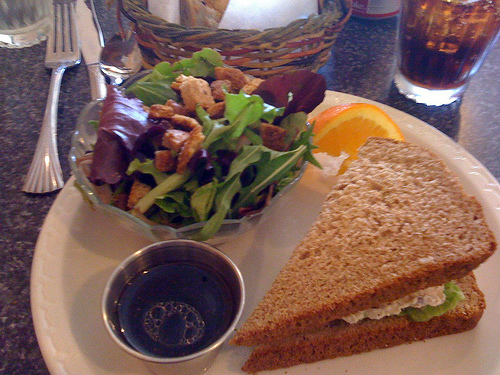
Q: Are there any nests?
A: No, there are no nests.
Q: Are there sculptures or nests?
A: No, there are no nests or sculptures.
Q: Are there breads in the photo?
A: Yes, there is a bread.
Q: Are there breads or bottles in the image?
A: Yes, there is a bread.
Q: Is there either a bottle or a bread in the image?
A: Yes, there is a bread.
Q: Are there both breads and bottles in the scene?
A: No, there is a bread but no bottles.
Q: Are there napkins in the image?
A: No, there are no napkins.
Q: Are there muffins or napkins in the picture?
A: No, there are no napkins or muffins.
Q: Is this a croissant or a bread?
A: This is a bread.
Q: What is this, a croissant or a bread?
A: This is a bread.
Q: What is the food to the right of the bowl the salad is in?
A: The food is a bread.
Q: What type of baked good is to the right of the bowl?
A: The food is a bread.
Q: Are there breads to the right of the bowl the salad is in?
A: Yes, there is a bread to the right of the bowl.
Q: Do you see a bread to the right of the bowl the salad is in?
A: Yes, there is a bread to the right of the bowl.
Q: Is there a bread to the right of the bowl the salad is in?
A: Yes, there is a bread to the right of the bowl.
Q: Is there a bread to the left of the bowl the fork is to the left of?
A: No, the bread is to the right of the bowl.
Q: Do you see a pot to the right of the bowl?
A: No, there is a bread to the right of the bowl.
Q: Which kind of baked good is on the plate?
A: The food is a bread.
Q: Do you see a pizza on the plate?
A: No, there is a bread on the plate.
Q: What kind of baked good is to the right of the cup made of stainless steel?
A: The food is a bread.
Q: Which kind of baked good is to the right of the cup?
A: The food is a bread.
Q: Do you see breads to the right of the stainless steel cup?
A: Yes, there is a bread to the right of the cup.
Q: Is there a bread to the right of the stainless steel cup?
A: Yes, there is a bread to the right of the cup.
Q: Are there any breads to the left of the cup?
A: No, the bread is to the right of the cup.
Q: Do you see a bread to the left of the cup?
A: No, the bread is to the right of the cup.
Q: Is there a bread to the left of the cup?
A: No, the bread is to the right of the cup.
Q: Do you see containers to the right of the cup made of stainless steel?
A: No, there is a bread to the right of the cup.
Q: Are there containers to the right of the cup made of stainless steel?
A: No, there is a bread to the right of the cup.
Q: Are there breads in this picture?
A: Yes, there is a bread.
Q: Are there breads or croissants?
A: Yes, there is a bread.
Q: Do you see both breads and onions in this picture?
A: No, there is a bread but no onions.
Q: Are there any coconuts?
A: No, there are no coconuts.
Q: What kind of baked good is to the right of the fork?
A: The food is a bread.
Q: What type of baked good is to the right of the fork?
A: The food is a bread.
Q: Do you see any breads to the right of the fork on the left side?
A: Yes, there is a bread to the right of the fork.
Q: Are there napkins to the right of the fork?
A: No, there is a bread to the right of the fork.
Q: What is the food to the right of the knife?
A: The food is a bread.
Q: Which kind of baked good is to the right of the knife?
A: The food is a bread.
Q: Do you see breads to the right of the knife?
A: Yes, there is a bread to the right of the knife.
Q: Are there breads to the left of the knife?
A: No, the bread is to the right of the knife.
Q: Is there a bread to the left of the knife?
A: No, the bread is to the right of the knife.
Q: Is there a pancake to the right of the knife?
A: No, there is a bread to the right of the knife.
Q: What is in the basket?
A: The bread is in the basket.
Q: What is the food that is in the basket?
A: The food is a bread.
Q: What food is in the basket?
A: The food is a bread.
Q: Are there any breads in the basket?
A: Yes, there is a bread in the basket.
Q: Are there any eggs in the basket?
A: No, there is a bread in the basket.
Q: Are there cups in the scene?
A: Yes, there is a cup.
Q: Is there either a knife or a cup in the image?
A: Yes, there is a cup.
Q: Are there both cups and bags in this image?
A: No, there is a cup but no bags.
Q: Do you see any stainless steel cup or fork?
A: Yes, there is a stainless steel cup.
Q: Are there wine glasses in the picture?
A: No, there are no wine glasses.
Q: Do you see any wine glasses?
A: No, there are no wine glasses.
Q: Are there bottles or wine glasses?
A: No, there are no wine glasses or bottles.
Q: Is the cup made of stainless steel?
A: Yes, the cup is made of stainless steel.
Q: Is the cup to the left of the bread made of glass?
A: No, the cup is made of stainless steel.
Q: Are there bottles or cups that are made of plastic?
A: No, there is a cup but it is made of stainless steel.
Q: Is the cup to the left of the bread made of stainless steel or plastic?
A: The cup is made of stainless steel.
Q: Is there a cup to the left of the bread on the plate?
A: Yes, there is a cup to the left of the bread.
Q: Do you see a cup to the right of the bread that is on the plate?
A: No, the cup is to the left of the bread.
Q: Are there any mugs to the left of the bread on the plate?
A: No, there is a cup to the left of the bread.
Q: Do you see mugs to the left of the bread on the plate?
A: No, there is a cup to the left of the bread.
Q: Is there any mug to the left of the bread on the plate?
A: No, there is a cup to the left of the bread.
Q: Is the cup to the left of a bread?
A: Yes, the cup is to the left of a bread.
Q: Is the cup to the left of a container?
A: No, the cup is to the left of a bread.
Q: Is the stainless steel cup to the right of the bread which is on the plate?
A: No, the cup is to the left of the bread.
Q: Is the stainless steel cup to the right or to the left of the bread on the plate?
A: The cup is to the left of the bread.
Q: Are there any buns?
A: No, there are no buns.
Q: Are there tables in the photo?
A: Yes, there is a table.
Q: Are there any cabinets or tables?
A: Yes, there is a table.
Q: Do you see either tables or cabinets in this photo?
A: Yes, there is a table.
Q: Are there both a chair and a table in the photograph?
A: No, there is a table but no chairs.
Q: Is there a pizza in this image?
A: No, there are no pizzas.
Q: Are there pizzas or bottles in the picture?
A: No, there are no pizzas or bottles.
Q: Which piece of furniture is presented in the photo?
A: The piece of furniture is a table.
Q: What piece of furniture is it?
A: The piece of furniture is a table.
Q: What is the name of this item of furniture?
A: That is a table.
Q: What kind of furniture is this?
A: That is a table.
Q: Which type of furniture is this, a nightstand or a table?
A: That is a table.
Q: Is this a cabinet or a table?
A: This is a table.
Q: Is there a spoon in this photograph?
A: Yes, there is a spoon.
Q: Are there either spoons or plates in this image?
A: Yes, there is a spoon.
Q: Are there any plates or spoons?
A: Yes, there is a spoon.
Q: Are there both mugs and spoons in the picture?
A: No, there is a spoon but no mugs.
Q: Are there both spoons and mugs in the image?
A: No, there is a spoon but no mugs.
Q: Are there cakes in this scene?
A: No, there are no cakes.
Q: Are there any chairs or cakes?
A: No, there are no cakes or chairs.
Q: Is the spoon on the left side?
A: Yes, the spoon is on the left of the image.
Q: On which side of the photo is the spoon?
A: The spoon is on the left of the image.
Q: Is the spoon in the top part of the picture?
A: Yes, the spoon is in the top of the image.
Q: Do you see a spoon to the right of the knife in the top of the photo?
A: Yes, there is a spoon to the right of the knife.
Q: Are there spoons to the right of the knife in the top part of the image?
A: Yes, there is a spoon to the right of the knife.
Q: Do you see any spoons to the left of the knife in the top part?
A: No, the spoon is to the right of the knife.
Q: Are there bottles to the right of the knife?
A: No, there is a spoon to the right of the knife.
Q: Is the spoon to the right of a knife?
A: Yes, the spoon is to the right of a knife.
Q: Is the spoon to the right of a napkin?
A: No, the spoon is to the right of a knife.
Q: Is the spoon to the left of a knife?
A: No, the spoon is to the right of a knife.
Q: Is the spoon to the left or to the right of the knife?
A: The spoon is to the right of the knife.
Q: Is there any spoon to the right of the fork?
A: Yes, there is a spoon to the right of the fork.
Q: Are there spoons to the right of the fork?
A: Yes, there is a spoon to the right of the fork.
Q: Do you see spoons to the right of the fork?
A: Yes, there is a spoon to the right of the fork.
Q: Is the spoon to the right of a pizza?
A: No, the spoon is to the right of the fork.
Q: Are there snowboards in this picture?
A: No, there are no snowboards.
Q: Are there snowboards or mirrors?
A: No, there are no snowboards or mirrors.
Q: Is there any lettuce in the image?
A: Yes, there is lettuce.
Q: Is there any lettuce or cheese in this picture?
A: Yes, there is lettuce.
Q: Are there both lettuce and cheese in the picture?
A: No, there is lettuce but no cheese.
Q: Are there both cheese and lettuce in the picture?
A: No, there is lettuce but no cheese.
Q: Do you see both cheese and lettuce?
A: No, there is lettuce but no cheese.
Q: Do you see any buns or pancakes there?
A: No, there are no buns or pancakes.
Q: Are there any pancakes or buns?
A: No, there are no buns or pancakes.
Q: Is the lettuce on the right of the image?
A: Yes, the lettuce is on the right of the image.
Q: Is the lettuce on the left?
A: No, the lettuce is on the right of the image.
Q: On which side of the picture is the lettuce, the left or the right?
A: The lettuce is on the right of the image.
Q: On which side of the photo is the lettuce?
A: The lettuce is on the right of the image.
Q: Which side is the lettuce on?
A: The lettuce is on the right of the image.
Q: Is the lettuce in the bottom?
A: Yes, the lettuce is in the bottom of the image.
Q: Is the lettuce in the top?
A: No, the lettuce is in the bottom of the image.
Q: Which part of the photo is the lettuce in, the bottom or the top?
A: The lettuce is in the bottom of the image.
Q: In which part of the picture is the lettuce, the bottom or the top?
A: The lettuce is in the bottom of the image.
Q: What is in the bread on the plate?
A: The lettuce is in the bread.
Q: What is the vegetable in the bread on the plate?
A: The vegetable is lettuce.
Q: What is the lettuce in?
A: The lettuce is in the bread.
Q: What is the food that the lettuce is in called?
A: The food is a bread.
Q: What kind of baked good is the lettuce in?
A: The lettuce is in the bread.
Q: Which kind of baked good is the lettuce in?
A: The lettuce is in the bread.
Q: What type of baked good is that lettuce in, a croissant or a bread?
A: The lettuce is in a bread.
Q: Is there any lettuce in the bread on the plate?
A: Yes, there is lettuce in the bread.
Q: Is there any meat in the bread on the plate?
A: No, there is lettuce in the bread.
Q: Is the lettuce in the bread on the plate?
A: Yes, the lettuce is in the bread.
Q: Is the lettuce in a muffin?
A: No, the lettuce is in the bread.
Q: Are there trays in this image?
A: No, there are no trays.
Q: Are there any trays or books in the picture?
A: No, there are no trays or books.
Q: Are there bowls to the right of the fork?
A: Yes, there is a bowl to the right of the fork.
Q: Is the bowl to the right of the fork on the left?
A: Yes, the bowl is to the right of the fork.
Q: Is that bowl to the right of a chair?
A: No, the bowl is to the right of the fork.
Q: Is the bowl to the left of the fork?
A: No, the bowl is to the right of the fork.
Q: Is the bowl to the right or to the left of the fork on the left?
A: The bowl is to the right of the fork.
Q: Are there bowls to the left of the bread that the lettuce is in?
A: Yes, there is a bowl to the left of the bread.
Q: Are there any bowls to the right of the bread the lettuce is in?
A: No, the bowl is to the left of the bread.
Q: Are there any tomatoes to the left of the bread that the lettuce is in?
A: No, there is a bowl to the left of the bread.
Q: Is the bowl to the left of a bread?
A: Yes, the bowl is to the left of a bread.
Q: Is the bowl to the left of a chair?
A: No, the bowl is to the left of a bread.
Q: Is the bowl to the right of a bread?
A: No, the bowl is to the left of a bread.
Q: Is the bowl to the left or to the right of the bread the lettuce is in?
A: The bowl is to the left of the bread.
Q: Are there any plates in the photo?
A: Yes, there is a plate.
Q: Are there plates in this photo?
A: Yes, there is a plate.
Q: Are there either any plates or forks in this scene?
A: Yes, there is a plate.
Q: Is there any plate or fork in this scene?
A: Yes, there is a plate.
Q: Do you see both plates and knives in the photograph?
A: Yes, there are both a plate and a knife.